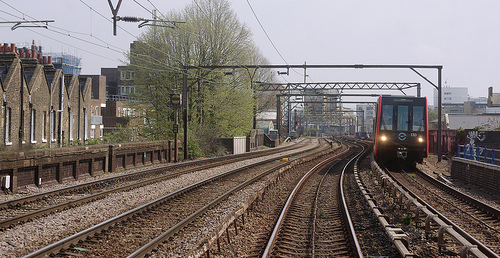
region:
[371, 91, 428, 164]
a train on the tracks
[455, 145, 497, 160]
blue metal railing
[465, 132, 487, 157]
white spray paint on the wall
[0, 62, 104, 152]
pointed roofs on the houses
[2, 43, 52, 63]
red smoke vents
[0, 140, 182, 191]
a brick wall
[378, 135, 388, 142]
the headlight is on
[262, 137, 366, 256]
train track is empty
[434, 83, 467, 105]
a large white building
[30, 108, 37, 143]
white framed window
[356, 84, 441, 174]
red and black train on train tracks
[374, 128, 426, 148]
two bright headlights on front of train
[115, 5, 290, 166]
green trees on side of train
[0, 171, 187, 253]
gravel on ground surrounding train tracks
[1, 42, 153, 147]
brick houses lining train tracks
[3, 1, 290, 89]
black power lines in sky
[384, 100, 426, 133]
windshield on front of train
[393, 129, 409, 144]
round blue logo on front of train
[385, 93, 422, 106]
digital window on front of the train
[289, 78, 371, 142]
citsyscape in horizon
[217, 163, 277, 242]
The tracks are made of metal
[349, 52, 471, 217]
Train is on the tracks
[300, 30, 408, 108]
The sky is cloudy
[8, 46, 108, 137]
Building beside the tracks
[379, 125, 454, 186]
Lights on front of the train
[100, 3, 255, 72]
Power lines over the tracks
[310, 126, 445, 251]
Shadow on the tracks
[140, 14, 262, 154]
Trees beside the track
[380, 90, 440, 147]
Windshield on front of train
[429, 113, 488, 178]
Fence beside the tracks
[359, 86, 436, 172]
red and black train on train track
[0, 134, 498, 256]
four rows of train tracks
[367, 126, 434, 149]
bright headlights on front of train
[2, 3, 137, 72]
black power lines in sky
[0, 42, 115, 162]
line of houses lining train tracks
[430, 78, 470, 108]
top of tall white building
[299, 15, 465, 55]
grey overcast sky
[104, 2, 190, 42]
metal structure in air with power lines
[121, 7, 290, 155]
tall green trees bordering train tracks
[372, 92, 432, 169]
red and black caboose on train track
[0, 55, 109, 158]
row of buildings by train tracks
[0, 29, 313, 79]
overhead wires over train tracks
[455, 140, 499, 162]
blue metal fence by train tracks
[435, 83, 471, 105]
white building in the distance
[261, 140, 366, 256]
second train track from the right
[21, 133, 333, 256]
second train track from the left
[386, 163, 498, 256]
train track on the far right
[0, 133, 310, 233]
train track on the far left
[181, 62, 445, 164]
over head metal bar